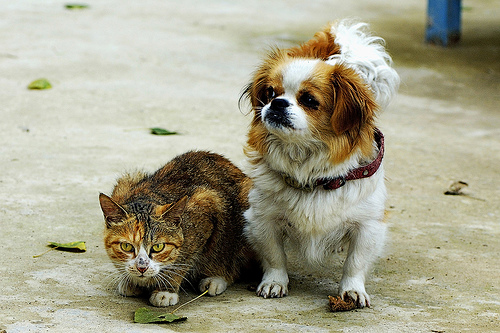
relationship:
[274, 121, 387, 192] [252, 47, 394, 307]
collar of dog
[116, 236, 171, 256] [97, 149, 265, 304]
eyes of animals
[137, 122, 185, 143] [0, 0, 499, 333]
leaf on concrete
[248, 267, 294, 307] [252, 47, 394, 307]
paw of dog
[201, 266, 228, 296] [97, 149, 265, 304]
paw of animals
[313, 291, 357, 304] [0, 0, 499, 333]
leaf on concrete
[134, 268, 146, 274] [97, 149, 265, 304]
nose of animals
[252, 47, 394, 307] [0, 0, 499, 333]
dog on concrete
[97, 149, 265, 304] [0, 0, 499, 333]
animals on concrete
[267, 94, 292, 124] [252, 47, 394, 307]
nose of dog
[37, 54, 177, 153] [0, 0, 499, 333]
leaves on concrete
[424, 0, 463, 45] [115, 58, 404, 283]
leg behind animals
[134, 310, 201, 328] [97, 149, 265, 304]
leaf next to animals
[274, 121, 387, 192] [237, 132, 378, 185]
collar around neck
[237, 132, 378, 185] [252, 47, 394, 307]
neck of dog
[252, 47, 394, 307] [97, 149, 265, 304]
dog and animals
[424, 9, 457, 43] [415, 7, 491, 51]
leg of table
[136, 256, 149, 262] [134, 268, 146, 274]
dots on nose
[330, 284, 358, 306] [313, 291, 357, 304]
paw on leaf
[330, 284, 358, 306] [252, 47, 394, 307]
paw of dog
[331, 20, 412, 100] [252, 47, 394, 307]
tail of dog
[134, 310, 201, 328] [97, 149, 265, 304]
leaf in front of animals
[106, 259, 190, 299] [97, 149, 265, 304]
whiskers on animals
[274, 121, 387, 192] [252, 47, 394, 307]
collar on dog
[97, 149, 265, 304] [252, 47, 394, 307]
animals and dog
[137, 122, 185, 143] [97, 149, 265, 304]
leaf next to animals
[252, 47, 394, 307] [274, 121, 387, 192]
dog wearing collar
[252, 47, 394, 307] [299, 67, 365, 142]
dog has patches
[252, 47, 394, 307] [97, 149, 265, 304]
dog bigger than animals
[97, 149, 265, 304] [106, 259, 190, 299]
animals has whiskers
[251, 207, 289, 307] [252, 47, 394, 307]
leg of dog